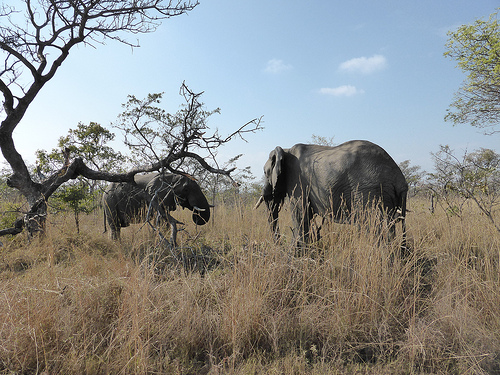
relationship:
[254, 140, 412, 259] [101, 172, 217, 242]
elephant facing another elephant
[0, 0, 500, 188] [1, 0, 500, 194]
clouds in sky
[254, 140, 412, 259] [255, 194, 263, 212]
elephant has a tusk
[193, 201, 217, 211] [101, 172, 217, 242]
tusks on elephant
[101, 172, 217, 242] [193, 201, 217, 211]
elephant has tusks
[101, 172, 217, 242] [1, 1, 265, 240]
elephant next to tree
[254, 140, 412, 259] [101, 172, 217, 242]
elephant next to another elephant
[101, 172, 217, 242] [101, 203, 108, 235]
elephant has a tail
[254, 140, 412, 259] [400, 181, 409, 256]
elephant has a tail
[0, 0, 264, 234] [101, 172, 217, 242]
branches near elephant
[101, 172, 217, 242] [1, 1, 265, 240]
elephant under tree